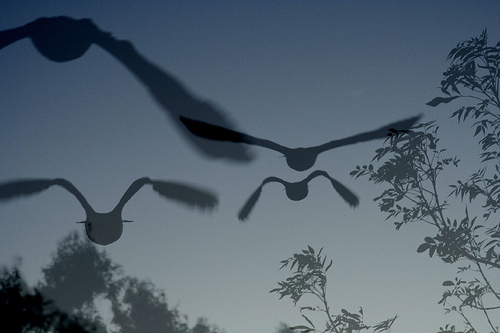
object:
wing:
[1, 177, 92, 213]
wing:
[84, 25, 257, 165]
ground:
[432, 142, 454, 161]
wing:
[318, 112, 427, 152]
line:
[122, 219, 133, 222]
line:
[75, 220, 86, 224]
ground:
[410, 151, 458, 194]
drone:
[176, 112, 429, 173]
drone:
[235, 169, 360, 223]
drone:
[5, 174, 223, 245]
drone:
[5, 16, 256, 164]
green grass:
[227, 163, 369, 228]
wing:
[309, 168, 355, 204]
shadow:
[0, 12, 260, 166]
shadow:
[178, 107, 426, 172]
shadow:
[3, 173, 221, 247]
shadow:
[233, 168, 359, 218]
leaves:
[348, 26, 497, 333]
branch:
[421, 206, 498, 272]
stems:
[429, 172, 449, 230]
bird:
[2, 14, 259, 162]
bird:
[233, 164, 359, 223]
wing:
[178, 115, 286, 157]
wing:
[236, 175, 284, 220]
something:
[0, 175, 221, 247]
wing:
[122, 174, 221, 216]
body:
[284, 180, 308, 202]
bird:
[0, 175, 220, 245]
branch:
[269, 244, 397, 333]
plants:
[270, 21, 500, 333]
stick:
[75, 219, 134, 224]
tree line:
[2, 228, 226, 333]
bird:
[177, 112, 428, 171]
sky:
[0, 1, 499, 331]